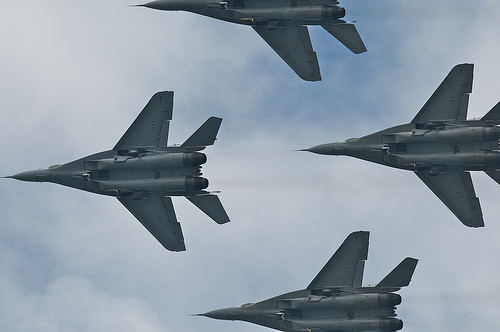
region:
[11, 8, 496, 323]
jets flying against cloudy blue sky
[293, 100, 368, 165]
pointed nose of jet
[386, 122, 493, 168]
cylinders between flat panel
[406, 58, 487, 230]
curved edges of wings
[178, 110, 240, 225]
flared geometric tail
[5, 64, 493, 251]
jet following the lead of jet in front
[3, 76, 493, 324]
jet flying under two jets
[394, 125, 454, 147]
angled wiring under cylinder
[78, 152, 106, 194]
slanted and open rectangular panels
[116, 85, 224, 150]
space between wing and tail sections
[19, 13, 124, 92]
The cloud is white.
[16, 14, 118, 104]
The cloud is in the sky.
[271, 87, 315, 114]
The sky is blue.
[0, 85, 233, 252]
The jet is in the sky.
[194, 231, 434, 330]
The jet is flying.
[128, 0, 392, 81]
The jet is gray in color.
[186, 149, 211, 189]
The jet engines are black in color.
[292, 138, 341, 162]
The head of the jet has a point.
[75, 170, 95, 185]
The wheel on the jet is round.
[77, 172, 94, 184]
The wheel on the jet is black.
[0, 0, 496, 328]
the airplanes in the sky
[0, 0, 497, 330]
the airplane in mid air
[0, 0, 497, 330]
the clouds in the sky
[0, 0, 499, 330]
the blue sky with clouds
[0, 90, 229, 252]
the airplane in mid air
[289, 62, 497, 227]
the airplane in mid air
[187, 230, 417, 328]
the airplane in mid air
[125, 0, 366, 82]
the airplane in mid air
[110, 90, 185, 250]
the wings on the airplane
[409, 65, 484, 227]
the wings on the airplane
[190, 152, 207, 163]
engine on the jet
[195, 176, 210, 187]
engine on the jet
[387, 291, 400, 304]
engine on the jet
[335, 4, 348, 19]
engine on the jet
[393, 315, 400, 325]
engine on the jet plane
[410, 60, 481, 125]
wing on the jet plane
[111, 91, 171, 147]
wing on the jet plane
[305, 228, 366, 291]
wing on the jet plane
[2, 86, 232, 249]
wing on the jet plane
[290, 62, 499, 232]
wing on the jet plane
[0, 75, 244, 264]
Plane in the air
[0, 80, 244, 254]
Plane is in the air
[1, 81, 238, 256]
Airplane in the air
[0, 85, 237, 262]
Airplane is in the air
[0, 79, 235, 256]
Fighter plane in the air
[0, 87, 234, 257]
Fighter plane is in the air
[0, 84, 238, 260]
Fighter jet in the air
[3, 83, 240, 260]
Fighter jet is in the air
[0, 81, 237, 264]
Plane up in the air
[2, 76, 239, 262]
Plane is up in the air